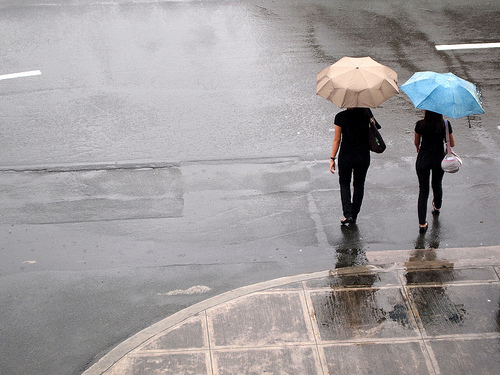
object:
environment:
[0, 0, 499, 373]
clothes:
[334, 107, 381, 217]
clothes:
[413, 119, 452, 225]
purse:
[439, 119, 462, 173]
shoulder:
[438, 119, 450, 131]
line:
[433, 42, 499, 51]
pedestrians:
[330, 107, 382, 225]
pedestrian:
[414, 110, 455, 231]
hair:
[422, 110, 444, 134]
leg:
[416, 165, 428, 223]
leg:
[430, 168, 443, 210]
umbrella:
[400, 70, 486, 119]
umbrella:
[314, 55, 400, 108]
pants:
[415, 155, 444, 224]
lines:
[0, 69, 43, 81]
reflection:
[390, 220, 467, 328]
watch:
[330, 158, 335, 160]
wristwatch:
[329, 156, 337, 160]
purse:
[364, 107, 387, 153]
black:
[347, 134, 362, 148]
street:
[0, 0, 499, 374]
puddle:
[293, 242, 370, 271]